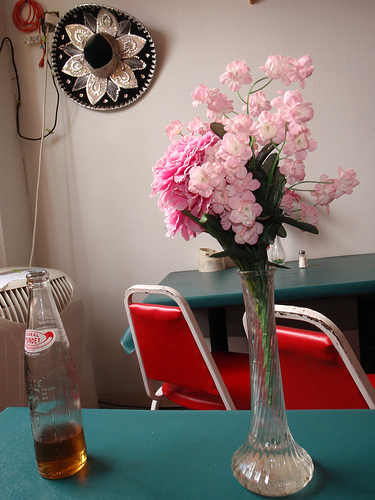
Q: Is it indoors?
A: Yes, it is indoors.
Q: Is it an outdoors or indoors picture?
A: It is indoors.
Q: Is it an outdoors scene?
A: No, it is indoors.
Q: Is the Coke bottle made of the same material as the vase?
A: Yes, both the bottle and the vase are made of glass.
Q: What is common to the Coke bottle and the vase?
A: The material, both the bottle and the vase are glass.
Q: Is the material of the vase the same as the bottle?
A: Yes, both the vase and the bottle are made of glass.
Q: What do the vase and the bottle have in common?
A: The material, both the vase and the bottle are glass.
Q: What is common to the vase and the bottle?
A: The material, both the vase and the bottle are glass.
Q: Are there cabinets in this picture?
A: No, there are no cabinets.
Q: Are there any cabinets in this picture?
A: No, there are no cabinets.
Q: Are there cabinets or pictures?
A: No, there are no cabinets or pictures.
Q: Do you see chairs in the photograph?
A: Yes, there is a chair.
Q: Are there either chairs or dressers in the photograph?
A: Yes, there is a chair.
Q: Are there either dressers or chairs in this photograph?
A: Yes, there is a chair.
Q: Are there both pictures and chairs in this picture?
A: No, there is a chair but no pictures.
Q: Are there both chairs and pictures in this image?
A: No, there is a chair but no pictures.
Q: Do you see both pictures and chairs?
A: No, there is a chair but no pictures.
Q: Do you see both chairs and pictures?
A: No, there is a chair but no pictures.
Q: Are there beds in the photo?
A: No, there are no beds.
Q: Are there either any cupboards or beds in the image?
A: No, there are no beds or cupboards.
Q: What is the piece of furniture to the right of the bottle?
A: The piece of furniture is a chair.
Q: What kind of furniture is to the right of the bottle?
A: The piece of furniture is a chair.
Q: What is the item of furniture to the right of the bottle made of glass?
A: The piece of furniture is a chair.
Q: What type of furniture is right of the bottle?
A: The piece of furniture is a chair.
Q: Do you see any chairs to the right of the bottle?
A: Yes, there is a chair to the right of the bottle.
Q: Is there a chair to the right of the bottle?
A: Yes, there is a chair to the right of the bottle.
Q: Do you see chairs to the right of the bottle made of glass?
A: Yes, there is a chair to the right of the bottle.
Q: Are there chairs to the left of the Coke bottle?
A: No, the chair is to the right of the bottle.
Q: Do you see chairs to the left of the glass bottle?
A: No, the chair is to the right of the bottle.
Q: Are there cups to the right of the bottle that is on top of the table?
A: No, there is a chair to the right of the bottle.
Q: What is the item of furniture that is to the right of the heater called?
A: The piece of furniture is a chair.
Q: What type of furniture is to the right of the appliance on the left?
A: The piece of furniture is a chair.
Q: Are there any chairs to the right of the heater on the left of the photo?
A: Yes, there is a chair to the right of the heater.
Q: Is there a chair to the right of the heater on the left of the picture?
A: Yes, there is a chair to the right of the heater.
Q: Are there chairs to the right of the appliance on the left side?
A: Yes, there is a chair to the right of the heater.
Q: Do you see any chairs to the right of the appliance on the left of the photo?
A: Yes, there is a chair to the right of the heater.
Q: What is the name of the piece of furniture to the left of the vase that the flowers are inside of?
A: The piece of furniture is a chair.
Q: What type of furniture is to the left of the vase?
A: The piece of furniture is a chair.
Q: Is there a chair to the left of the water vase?
A: Yes, there is a chair to the left of the vase.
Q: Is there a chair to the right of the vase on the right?
A: No, the chair is to the left of the vase.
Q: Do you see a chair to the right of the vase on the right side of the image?
A: No, the chair is to the left of the vase.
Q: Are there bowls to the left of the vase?
A: No, there is a chair to the left of the vase.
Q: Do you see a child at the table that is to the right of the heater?
A: No, there is a chair at the table.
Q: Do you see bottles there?
A: Yes, there is a bottle.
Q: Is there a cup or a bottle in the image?
A: Yes, there is a bottle.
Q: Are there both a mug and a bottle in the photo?
A: No, there is a bottle but no mugs.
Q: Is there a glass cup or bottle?
A: Yes, there is a glass bottle.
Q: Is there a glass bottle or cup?
A: Yes, there is a glass bottle.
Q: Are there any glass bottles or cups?
A: Yes, there is a glass bottle.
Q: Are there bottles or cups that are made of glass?
A: Yes, the bottle is made of glass.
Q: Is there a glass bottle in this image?
A: Yes, there is a bottle that is made of glass.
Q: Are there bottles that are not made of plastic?
A: Yes, there is a bottle that is made of glass.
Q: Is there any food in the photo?
A: No, there is no food.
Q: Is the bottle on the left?
A: Yes, the bottle is on the left of the image.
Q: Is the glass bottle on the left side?
A: Yes, the bottle is on the left of the image.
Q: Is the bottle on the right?
A: No, the bottle is on the left of the image.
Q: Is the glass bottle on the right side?
A: No, the bottle is on the left of the image.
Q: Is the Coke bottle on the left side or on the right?
A: The bottle is on the left of the image.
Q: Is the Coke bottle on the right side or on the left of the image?
A: The bottle is on the left of the image.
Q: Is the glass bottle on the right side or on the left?
A: The bottle is on the left of the image.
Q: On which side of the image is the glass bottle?
A: The bottle is on the left of the image.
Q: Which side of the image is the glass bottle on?
A: The bottle is on the left of the image.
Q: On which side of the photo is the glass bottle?
A: The bottle is on the left of the image.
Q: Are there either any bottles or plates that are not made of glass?
A: No, there is a bottle but it is made of glass.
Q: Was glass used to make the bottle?
A: Yes, the bottle is made of glass.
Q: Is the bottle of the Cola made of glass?
A: Yes, the bottle is made of glass.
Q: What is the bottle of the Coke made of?
A: The bottle is made of glass.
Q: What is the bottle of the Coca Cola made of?
A: The bottle is made of glass.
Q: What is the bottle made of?
A: The bottle is made of glass.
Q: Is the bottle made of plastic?
A: No, the bottle is made of glass.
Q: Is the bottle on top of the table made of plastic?
A: No, the bottle is made of glass.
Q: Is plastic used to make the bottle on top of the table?
A: No, the bottle is made of glass.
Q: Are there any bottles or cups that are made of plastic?
A: No, there is a bottle but it is made of glass.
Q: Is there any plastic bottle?
A: No, there is a bottle but it is made of glass.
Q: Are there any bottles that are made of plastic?
A: No, there is a bottle but it is made of glass.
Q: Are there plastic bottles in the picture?
A: No, there is a bottle but it is made of glass.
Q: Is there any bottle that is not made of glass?
A: No, there is a bottle but it is made of glass.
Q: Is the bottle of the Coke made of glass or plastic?
A: The bottle is made of glass.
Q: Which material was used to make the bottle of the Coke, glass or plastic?
A: The bottle is made of glass.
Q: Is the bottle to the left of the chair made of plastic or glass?
A: The bottle is made of glass.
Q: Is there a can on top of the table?
A: No, there is a bottle on top of the table.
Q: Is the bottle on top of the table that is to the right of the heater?
A: Yes, the bottle is on top of the table.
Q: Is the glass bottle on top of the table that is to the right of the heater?
A: Yes, the bottle is on top of the table.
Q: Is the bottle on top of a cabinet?
A: No, the bottle is on top of the table.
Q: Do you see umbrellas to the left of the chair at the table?
A: No, there is a bottle to the left of the chair.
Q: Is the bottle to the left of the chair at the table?
A: Yes, the bottle is to the left of the chair.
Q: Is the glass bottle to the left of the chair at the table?
A: Yes, the bottle is to the left of the chair.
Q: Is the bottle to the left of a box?
A: No, the bottle is to the left of the chair.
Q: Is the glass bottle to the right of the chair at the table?
A: No, the bottle is to the left of the chair.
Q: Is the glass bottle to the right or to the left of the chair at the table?
A: The bottle is to the left of the chair.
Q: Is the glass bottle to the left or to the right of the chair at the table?
A: The bottle is to the left of the chair.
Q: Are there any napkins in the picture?
A: No, there are no napkins.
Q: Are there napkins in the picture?
A: No, there are no napkins.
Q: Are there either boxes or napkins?
A: No, there are no napkins or boxes.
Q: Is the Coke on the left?
A: Yes, the Coke is on the left of the image.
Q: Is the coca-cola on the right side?
A: No, the coca-cola is on the left of the image.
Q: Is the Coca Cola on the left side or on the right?
A: The Coca Cola is on the left of the image.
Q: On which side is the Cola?
A: The Cola is on the left of the image.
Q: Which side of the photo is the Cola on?
A: The Cola is on the left of the image.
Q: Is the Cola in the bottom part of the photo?
A: Yes, the Cola is in the bottom of the image.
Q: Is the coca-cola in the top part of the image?
A: No, the coca-cola is in the bottom of the image.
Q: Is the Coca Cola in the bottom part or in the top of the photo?
A: The Coca Cola is in the bottom of the image.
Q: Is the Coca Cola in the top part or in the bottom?
A: The Coca Cola is in the bottom of the image.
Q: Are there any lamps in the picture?
A: No, there are no lamps.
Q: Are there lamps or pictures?
A: No, there are no lamps or pictures.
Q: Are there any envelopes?
A: No, there are no envelopes.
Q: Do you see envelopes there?
A: No, there are no envelopes.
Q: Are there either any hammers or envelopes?
A: No, there are no envelopes or hammers.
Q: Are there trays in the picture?
A: No, there are no trays.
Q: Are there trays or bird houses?
A: No, there are no trays or bird houses.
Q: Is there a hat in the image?
A: Yes, there is a hat.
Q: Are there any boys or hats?
A: Yes, there is a hat.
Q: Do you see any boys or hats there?
A: Yes, there is a hat.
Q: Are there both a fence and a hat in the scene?
A: No, there is a hat but no fences.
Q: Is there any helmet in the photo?
A: No, there are no helmets.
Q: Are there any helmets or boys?
A: No, there are no helmets or boys.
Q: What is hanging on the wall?
A: The hat is hanging on the wall.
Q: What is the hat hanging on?
A: The hat is hanging on the wall.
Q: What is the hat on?
A: The hat is on the wall.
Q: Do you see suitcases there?
A: No, there are no suitcases.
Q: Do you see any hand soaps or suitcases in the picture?
A: No, there are no suitcases or hand soaps.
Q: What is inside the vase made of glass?
A: The flowers are inside the vase.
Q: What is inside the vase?
A: The flowers are inside the vase.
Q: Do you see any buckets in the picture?
A: No, there are no buckets.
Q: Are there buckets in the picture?
A: No, there are no buckets.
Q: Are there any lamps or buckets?
A: No, there are no buckets or lamps.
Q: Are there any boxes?
A: No, there are no boxes.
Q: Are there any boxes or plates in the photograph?
A: No, there are no boxes or plates.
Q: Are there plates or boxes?
A: No, there are no boxes or plates.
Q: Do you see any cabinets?
A: No, there are no cabinets.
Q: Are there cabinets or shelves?
A: No, there are no cabinets or shelves.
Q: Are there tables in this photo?
A: Yes, there is a table.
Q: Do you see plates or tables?
A: Yes, there is a table.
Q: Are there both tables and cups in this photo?
A: No, there is a table but no cups.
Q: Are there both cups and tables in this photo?
A: No, there is a table but no cups.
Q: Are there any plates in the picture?
A: No, there are no plates.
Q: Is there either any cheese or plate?
A: No, there are no plates or cheese.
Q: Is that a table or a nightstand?
A: That is a table.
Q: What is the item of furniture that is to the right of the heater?
A: The piece of furniture is a table.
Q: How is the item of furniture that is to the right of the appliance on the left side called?
A: The piece of furniture is a table.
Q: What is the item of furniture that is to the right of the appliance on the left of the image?
A: The piece of furniture is a table.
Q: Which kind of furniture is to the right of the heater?
A: The piece of furniture is a table.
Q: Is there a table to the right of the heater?
A: Yes, there is a table to the right of the heater.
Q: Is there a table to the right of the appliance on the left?
A: Yes, there is a table to the right of the heater.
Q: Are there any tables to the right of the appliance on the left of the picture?
A: Yes, there is a table to the right of the heater.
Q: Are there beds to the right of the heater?
A: No, there is a table to the right of the heater.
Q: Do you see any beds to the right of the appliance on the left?
A: No, there is a table to the right of the heater.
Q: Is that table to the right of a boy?
A: No, the table is to the right of a heater.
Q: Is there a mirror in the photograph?
A: No, there are no mirrors.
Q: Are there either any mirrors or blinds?
A: No, there are no mirrors or blinds.